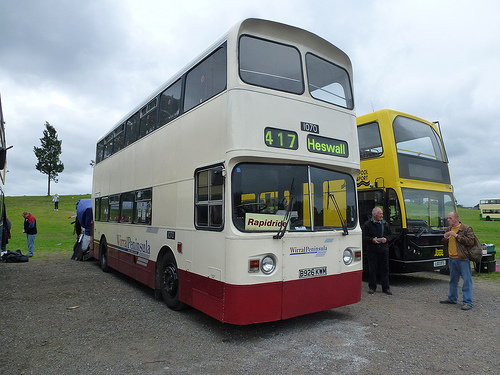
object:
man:
[362, 207, 394, 296]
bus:
[91, 16, 366, 326]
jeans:
[445, 257, 474, 307]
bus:
[356, 108, 459, 275]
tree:
[31, 121, 65, 197]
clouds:
[1, 2, 500, 207]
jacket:
[23, 213, 37, 235]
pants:
[368, 241, 390, 291]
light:
[260, 253, 276, 276]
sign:
[245, 212, 290, 231]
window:
[236, 32, 306, 95]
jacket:
[442, 222, 485, 262]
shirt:
[447, 223, 461, 259]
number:
[265, 131, 296, 148]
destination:
[307, 134, 349, 158]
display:
[263, 126, 349, 158]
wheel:
[157, 246, 187, 311]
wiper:
[273, 177, 296, 242]